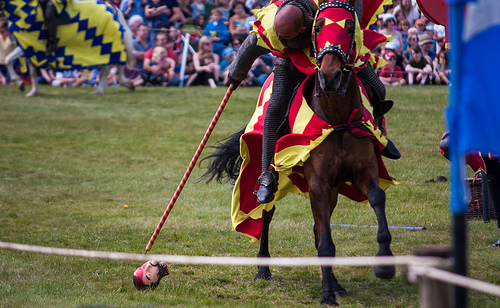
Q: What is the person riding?
A: A horse.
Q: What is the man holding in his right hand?
A: A red and white striped pole.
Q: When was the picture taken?
A: Daytime.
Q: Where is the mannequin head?
A: On the ground.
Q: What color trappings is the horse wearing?
A: Red and yellow.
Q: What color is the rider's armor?
A: Black.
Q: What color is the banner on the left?
A: Yellow and blue.